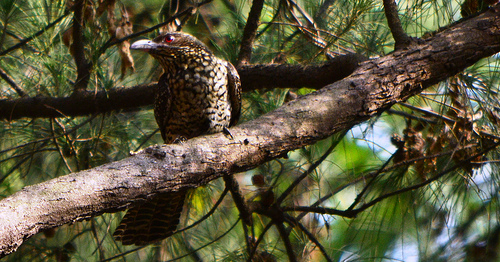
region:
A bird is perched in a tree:
[43, 20, 458, 231]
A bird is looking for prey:
[55, 11, 485, 223]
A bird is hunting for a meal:
[43, 5, 458, 226]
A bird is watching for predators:
[12, 10, 487, 235]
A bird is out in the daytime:
[15, 15, 498, 231]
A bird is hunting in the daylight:
[21, 10, 471, 225]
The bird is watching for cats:
[18, 13, 476, 224]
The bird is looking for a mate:
[5, 12, 495, 232]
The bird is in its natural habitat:
[15, 15, 481, 235]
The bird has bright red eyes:
[30, 15, 495, 210]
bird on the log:
[126, 28, 266, 169]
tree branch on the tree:
[260, 77, 352, 164]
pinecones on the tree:
[382, 125, 485, 172]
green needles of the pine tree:
[342, 196, 432, 240]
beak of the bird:
[119, 33, 162, 54]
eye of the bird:
[160, 32, 175, 47]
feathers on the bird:
[106, 195, 187, 255]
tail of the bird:
[105, 189, 197, 256]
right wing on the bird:
[218, 63, 252, 124]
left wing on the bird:
[150, 73, 169, 135]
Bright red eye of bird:
[155, 28, 200, 48]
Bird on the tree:
[69, 19, 247, 181]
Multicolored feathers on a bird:
[158, 59, 218, 122]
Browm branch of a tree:
[12, 174, 133, 217]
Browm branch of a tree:
[133, 138, 263, 171]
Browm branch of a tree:
[254, 99, 369, 139]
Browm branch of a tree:
[341, 40, 440, 101]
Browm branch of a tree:
[432, 8, 497, 53]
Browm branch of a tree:
[8, 77, 105, 117]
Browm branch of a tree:
[242, 53, 338, 83]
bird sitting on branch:
[111, 29, 243, 245]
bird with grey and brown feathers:
[111, 32, 251, 245]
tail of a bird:
[112, 186, 193, 243]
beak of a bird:
[132, 39, 157, 51]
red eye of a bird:
[163, 36, 175, 40]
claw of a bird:
[220, 125, 234, 140]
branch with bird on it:
[0, 9, 497, 249]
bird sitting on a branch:
[117, 28, 240, 248]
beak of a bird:
[132, 35, 163, 48]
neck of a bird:
[160, 49, 220, 71]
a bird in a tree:
[114, 29, 242, 248]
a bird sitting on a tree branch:
[110, 28, 247, 247]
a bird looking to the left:
[105, 28, 250, 249]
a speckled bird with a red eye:
[108, 24, 245, 246]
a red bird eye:
[161, 30, 176, 46]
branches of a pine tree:
[2, 1, 498, 260]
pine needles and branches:
[0, 2, 499, 259]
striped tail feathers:
[111, 181, 190, 243]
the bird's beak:
[124, 33, 158, 57]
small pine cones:
[386, 116, 483, 174]